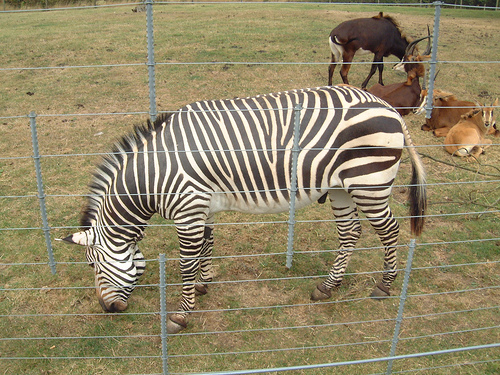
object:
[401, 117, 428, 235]
tail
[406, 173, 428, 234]
hair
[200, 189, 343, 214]
white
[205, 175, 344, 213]
belly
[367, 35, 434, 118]
animals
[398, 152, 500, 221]
sticks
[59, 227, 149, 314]
head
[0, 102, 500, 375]
fence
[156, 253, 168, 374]
metal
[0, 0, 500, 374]
grass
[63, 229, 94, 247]
ear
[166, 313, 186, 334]
hoof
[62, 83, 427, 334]
zebra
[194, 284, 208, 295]
hoof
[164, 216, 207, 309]
leg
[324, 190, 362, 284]
leg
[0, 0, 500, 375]
ground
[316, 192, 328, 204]
penis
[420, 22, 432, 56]
horns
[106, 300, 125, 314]
mouth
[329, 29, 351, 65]
butt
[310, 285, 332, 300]
hoof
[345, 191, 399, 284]
leg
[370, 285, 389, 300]
hoof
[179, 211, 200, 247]
legs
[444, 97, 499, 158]
animal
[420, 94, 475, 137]
animal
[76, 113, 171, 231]
mane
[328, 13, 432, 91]
animal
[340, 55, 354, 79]
legs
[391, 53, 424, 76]
head down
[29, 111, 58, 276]
bar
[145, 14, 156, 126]
bar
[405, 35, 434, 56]
horn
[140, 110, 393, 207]
stripes